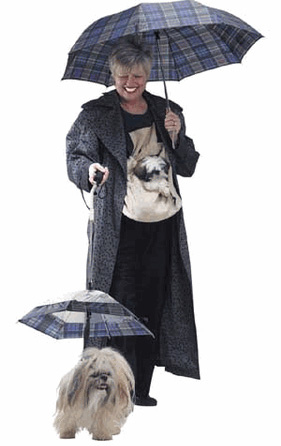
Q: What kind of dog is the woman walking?
A: A white dog with fluffy hair.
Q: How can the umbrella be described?
A: Purple and gray trimmed umbrella.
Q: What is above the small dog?
A: A clear plastic umbrella.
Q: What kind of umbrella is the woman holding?
A: A gray and purple plaid umbrella.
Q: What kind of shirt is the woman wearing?
A: A shirt with a picture of a dog.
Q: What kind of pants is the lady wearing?
A: Black pants.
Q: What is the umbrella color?
A: Grey and blue.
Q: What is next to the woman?
A: Dog.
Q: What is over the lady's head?
A: Umbrella.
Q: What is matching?
A: Umbrellas.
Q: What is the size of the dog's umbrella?
A: Tiny.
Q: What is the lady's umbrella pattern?
A: Plaid.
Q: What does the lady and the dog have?
A: Umbrellas.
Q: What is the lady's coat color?
A: Grey and black.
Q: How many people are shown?
A: One.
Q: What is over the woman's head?
A: Umbrella.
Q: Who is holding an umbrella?
A: Woman.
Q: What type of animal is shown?
A: Dog.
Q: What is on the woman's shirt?
A: Dog.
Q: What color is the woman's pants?
A: Black.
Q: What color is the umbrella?
A: Blue and gray.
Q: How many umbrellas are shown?
A: Two.